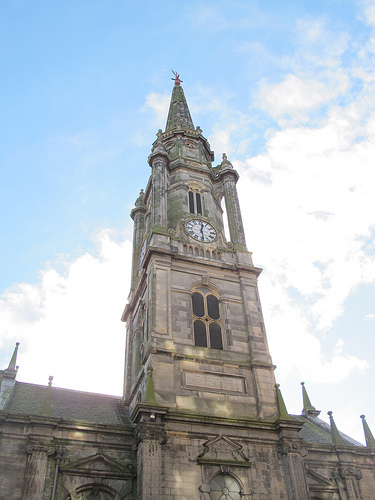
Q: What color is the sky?
A: Blue.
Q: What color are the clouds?
A: White.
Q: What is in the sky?
A: Clouds.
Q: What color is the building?
A: Brown.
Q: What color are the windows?
A: Black.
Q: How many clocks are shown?
A: 2.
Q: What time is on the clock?
A: 6:01.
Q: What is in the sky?
A: Clouds.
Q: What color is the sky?
A: Blue.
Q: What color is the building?
A: Tan.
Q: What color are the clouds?
A: White.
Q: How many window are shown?
A: 2.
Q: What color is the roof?
A: Gray.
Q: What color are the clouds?
A: White.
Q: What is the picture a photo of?
A: A building.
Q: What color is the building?
A: Tan.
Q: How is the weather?
A: Sunny.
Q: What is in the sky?
A: Clouds.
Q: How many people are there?
A: None.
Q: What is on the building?
A: A clock.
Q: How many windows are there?
A: Two.